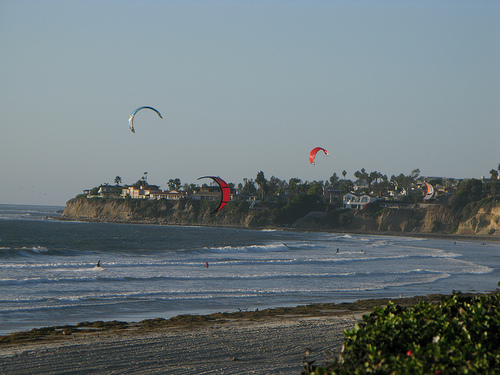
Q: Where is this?
A: This is at the ocean.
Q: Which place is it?
A: It is an ocean.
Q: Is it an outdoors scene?
A: Yes, it is outdoors.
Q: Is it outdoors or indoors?
A: It is outdoors.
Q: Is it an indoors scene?
A: No, it is outdoors.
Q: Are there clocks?
A: No, there are no clocks.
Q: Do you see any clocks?
A: No, there are no clocks.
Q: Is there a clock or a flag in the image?
A: No, there are no clocks or flags.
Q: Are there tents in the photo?
A: No, there are no tents.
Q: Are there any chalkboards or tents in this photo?
A: No, there are no tents or chalkboards.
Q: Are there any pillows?
A: No, there are no pillows.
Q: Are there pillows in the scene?
A: No, there are no pillows.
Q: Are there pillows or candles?
A: No, there are no pillows or candles.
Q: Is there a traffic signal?
A: No, there are no traffic lights.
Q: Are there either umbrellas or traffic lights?
A: No, there are no traffic lights or umbrellas.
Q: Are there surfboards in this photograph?
A: No, there are no surfboards.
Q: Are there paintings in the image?
A: No, there are no paintings.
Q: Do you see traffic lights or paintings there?
A: No, there are no paintings or traffic lights.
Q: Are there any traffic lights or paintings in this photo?
A: No, there are no paintings or traffic lights.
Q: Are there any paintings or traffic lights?
A: No, there are no paintings or traffic lights.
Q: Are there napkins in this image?
A: No, there are no napkins.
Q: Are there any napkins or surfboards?
A: No, there are no napkins or surfboards.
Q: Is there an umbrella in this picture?
A: No, there are no umbrellas.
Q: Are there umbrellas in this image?
A: No, there are no umbrellas.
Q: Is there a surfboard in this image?
A: No, there are no surfboards.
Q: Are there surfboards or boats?
A: No, there are no surfboards or boats.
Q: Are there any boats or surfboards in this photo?
A: No, there are no surfboards or boats.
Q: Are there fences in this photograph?
A: No, there are no fences.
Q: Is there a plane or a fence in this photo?
A: No, there are no fences or airplanes.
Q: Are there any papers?
A: No, there are no papers.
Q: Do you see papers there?
A: No, there are no papers.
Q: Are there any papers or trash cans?
A: No, there are no papers or trash cans.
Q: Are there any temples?
A: No, there are no temples.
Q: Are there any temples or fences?
A: No, there are no temples or fences.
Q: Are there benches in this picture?
A: No, there are no benches.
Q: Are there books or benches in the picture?
A: No, there are no benches or books.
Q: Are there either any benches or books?
A: No, there are no benches or books.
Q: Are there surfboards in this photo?
A: No, there are no surfboards.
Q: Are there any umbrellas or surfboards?
A: No, there are no surfboards or umbrellas.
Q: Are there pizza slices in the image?
A: No, there are no pizza slices.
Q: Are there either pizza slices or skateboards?
A: No, there are no pizza slices or skateboards.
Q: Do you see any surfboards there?
A: No, there are no surfboards.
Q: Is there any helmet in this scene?
A: No, there are no helmets.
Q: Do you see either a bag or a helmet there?
A: No, there are no helmets or bags.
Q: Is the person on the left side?
A: Yes, the person is on the left of the image.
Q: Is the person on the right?
A: No, the person is on the left of the image.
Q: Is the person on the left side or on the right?
A: The person is on the left of the image.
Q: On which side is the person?
A: The person is on the left of the image.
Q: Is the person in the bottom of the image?
A: Yes, the person is in the bottom of the image.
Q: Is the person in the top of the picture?
A: No, the person is in the bottom of the image.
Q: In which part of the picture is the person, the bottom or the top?
A: The person is in the bottom of the image.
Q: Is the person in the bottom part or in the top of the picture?
A: The person is in the bottom of the image.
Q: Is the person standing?
A: Yes, the person is standing.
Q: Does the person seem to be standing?
A: Yes, the person is standing.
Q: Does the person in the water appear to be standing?
A: Yes, the person is standing.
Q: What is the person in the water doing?
A: The person is standing.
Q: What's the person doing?
A: The person is standing.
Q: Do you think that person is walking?
A: No, the person is standing.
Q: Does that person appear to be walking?
A: No, the person is standing.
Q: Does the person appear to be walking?
A: No, the person is standing.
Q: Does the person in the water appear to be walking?
A: No, the person is standing.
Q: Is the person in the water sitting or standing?
A: The person is standing.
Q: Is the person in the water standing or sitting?
A: The person is standing.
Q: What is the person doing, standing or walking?
A: The person is standing.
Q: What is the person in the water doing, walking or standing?
A: The person is standing.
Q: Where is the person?
A: The person is in the water.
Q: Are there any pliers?
A: No, there are no pliers.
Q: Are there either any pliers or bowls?
A: No, there are no pliers or bowls.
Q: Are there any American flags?
A: No, there are no American flags.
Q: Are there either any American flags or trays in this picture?
A: No, there are no American flags or trays.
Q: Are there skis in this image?
A: No, there are no skis.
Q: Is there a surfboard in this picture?
A: No, there are no surfboards.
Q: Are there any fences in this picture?
A: No, there are no fences.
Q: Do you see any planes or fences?
A: No, there are no fences or planes.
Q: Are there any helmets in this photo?
A: No, there are no helmets.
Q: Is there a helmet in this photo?
A: No, there are no helmets.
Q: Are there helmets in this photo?
A: No, there are no helmets.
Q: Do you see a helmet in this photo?
A: No, there are no helmets.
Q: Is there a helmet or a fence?
A: No, there are no helmets or fences.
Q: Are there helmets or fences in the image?
A: No, there are no helmets or fences.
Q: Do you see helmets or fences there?
A: No, there are no helmets or fences.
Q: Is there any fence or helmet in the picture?
A: No, there are no helmets or fences.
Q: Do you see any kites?
A: Yes, there is a kite.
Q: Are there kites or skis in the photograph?
A: Yes, there is a kite.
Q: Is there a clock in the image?
A: No, there are no clocks.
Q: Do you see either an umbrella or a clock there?
A: No, there are no clocks or umbrellas.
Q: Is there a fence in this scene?
A: No, there are no fences.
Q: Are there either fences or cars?
A: No, there are no fences or cars.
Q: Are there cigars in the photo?
A: No, there are no cigars.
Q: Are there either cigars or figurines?
A: No, there are no cigars or figurines.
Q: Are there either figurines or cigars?
A: No, there are no cigars or figurines.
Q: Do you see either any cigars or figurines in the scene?
A: No, there are no cigars or figurines.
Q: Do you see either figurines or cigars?
A: No, there are no cigars or figurines.